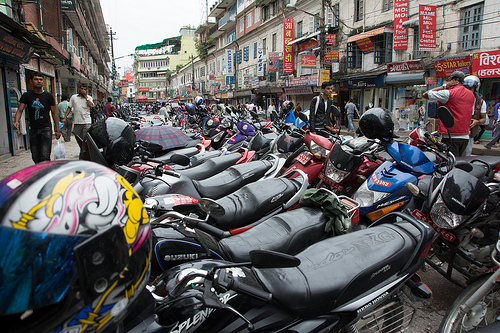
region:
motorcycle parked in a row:
[274, 235, 456, 311]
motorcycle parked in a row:
[218, 213, 382, 245]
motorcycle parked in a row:
[181, 181, 376, 209]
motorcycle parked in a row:
[181, 143, 301, 188]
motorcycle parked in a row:
[181, 147, 274, 169]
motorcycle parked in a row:
[183, 140, 243, 165]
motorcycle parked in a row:
[163, 143, 235, 157]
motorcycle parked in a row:
[193, 122, 225, 132]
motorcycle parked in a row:
[183, 108, 203, 128]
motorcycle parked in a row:
[166, 99, 193, 128]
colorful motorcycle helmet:
[1, 155, 146, 327]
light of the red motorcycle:
[299, 129, 330, 184]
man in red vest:
[420, 70, 474, 142]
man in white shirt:
[66, 81, 96, 146]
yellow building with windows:
[122, 41, 182, 100]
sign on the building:
[277, 18, 301, 80]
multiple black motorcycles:
[140, 155, 417, 329]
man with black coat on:
[309, 77, 335, 129]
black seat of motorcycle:
[291, 233, 413, 291]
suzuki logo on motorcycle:
[160, 243, 200, 268]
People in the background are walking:
[8, 65, 101, 170]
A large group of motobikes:
[105, 95, 496, 330]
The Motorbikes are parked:
[136, 98, 494, 331]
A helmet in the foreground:
[5, 149, 167, 331]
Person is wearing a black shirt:
[10, 85, 56, 140]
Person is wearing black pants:
[25, 120, 56, 160]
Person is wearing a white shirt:
[63, 86, 93, 126]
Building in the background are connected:
[169, 0, 496, 117]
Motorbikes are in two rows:
[116, 102, 499, 332]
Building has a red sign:
[278, 15, 301, 80]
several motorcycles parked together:
[137, 70, 489, 329]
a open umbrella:
[123, 118, 187, 155]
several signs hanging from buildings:
[138, 9, 462, 111]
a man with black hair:
[26, 70, 47, 98]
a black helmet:
[343, 99, 403, 171]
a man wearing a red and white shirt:
[433, 66, 472, 140]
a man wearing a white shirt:
[69, 82, 90, 126]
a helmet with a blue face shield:
[0, 168, 156, 320]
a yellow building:
[132, 24, 200, 96]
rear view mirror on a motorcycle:
[208, 247, 307, 276]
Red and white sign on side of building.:
[416, 6, 443, 55]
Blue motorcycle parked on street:
[352, 122, 445, 215]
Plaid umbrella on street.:
[132, 118, 192, 153]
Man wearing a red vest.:
[421, 68, 477, 148]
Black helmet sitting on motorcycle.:
[356, 105, 396, 146]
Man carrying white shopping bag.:
[15, 68, 67, 166]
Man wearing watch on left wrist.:
[66, 81, 96, 142]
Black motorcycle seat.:
[235, 206, 428, 313]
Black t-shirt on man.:
[15, 70, 63, 157]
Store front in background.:
[380, 63, 432, 143]